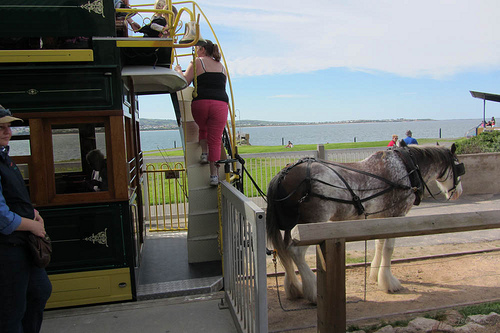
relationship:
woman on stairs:
[191, 53, 233, 177] [165, 77, 242, 263]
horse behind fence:
[268, 159, 462, 299] [206, 196, 285, 331]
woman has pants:
[191, 53, 233, 177] [185, 105, 233, 160]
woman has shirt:
[191, 53, 233, 177] [200, 62, 228, 109]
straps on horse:
[319, 151, 418, 211] [268, 159, 462, 299]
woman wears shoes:
[191, 53, 233, 177] [203, 147, 219, 190]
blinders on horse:
[450, 160, 467, 190] [268, 159, 462, 299]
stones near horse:
[380, 311, 495, 329] [268, 159, 462, 299]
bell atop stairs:
[181, 16, 207, 45] [165, 77, 242, 263]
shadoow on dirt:
[347, 277, 481, 325] [424, 253, 492, 306]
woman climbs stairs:
[191, 53, 233, 177] [165, 77, 242, 263]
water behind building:
[279, 119, 441, 143] [2, 11, 183, 301]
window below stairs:
[26, 110, 127, 198] [165, 77, 242, 263]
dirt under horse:
[424, 253, 492, 306] [268, 159, 462, 299]